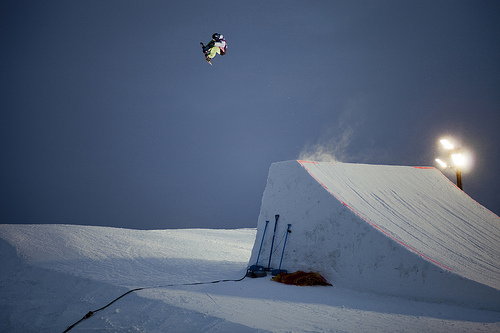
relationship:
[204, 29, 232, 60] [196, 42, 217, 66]
man on skis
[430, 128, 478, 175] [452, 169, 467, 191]
lights attached to pole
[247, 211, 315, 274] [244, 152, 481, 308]
equipment on side of ramp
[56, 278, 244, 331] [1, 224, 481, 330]
wire on ground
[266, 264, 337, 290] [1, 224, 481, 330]
cloth on ground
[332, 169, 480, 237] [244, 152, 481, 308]
snow on top of ramp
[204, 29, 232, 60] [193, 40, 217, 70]
man on snowboard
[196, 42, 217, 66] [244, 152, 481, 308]
skis rode off ramp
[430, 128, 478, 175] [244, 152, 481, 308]
lights illuminating ramp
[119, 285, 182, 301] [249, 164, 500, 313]
cord leading down hill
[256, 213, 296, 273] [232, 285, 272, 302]
poles lying on ramp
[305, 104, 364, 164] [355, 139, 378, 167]
dust flying off ramp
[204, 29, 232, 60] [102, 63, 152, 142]
man in air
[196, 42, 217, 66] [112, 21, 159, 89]
skis in air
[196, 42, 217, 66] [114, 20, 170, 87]
skis in air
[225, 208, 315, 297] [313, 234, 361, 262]
equipment by ramp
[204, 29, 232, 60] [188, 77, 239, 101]
man in midair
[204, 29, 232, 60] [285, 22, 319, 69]
man in air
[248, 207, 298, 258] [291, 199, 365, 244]
skis leaning against hill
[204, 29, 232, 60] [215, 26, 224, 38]
man wearing helmet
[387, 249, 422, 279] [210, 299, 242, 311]
snow covering ground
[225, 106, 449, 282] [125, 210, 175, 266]
picture on a mountain